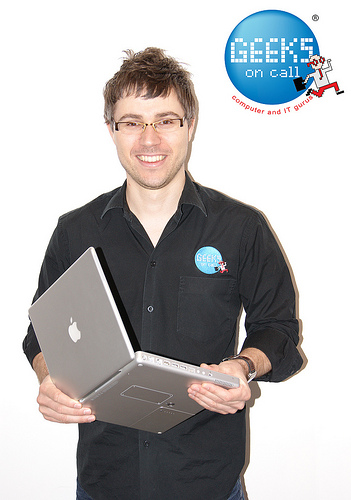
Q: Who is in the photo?
A: A man.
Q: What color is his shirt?
A: Black.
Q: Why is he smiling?
A: He is happy.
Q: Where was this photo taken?
A: In an office.